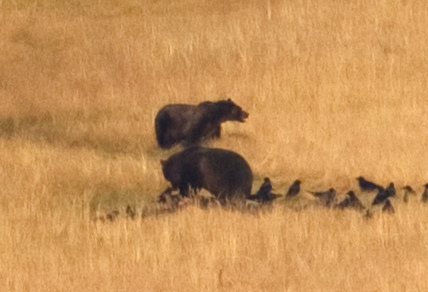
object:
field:
[3, 0, 423, 288]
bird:
[285, 179, 302, 202]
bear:
[155, 98, 250, 150]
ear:
[227, 98, 233, 103]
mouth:
[239, 113, 248, 122]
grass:
[29, 30, 428, 291]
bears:
[159, 148, 253, 208]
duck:
[306, 188, 336, 201]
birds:
[256, 177, 272, 195]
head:
[223, 98, 250, 123]